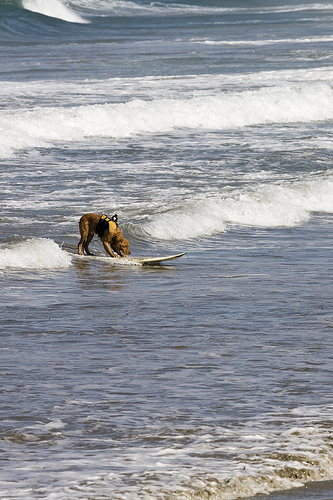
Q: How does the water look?
A: Very frothy.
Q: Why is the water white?
A: Crashed wave.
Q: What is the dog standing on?
A: Surfboard.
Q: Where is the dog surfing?
A: The ocean.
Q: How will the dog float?
A: Life jacket.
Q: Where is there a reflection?
A: Water surface.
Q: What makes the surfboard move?
A: Waves.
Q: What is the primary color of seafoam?
A: White.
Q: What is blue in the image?
A: Water.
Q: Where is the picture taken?
A: A beach.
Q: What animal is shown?
A: A dog.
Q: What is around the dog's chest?
A: A life jacket.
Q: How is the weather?
A: Sunny.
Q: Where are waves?
A: In the ocean.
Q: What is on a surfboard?
A: Dog.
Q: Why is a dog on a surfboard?
A: To surf.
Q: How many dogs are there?
A: One.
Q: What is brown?
A: A dog.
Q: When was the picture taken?
A: During the day.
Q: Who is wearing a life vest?
A: The dog.